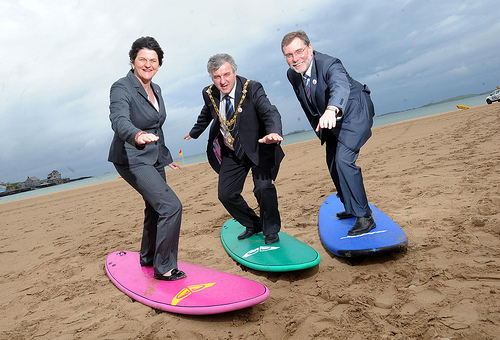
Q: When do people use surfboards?
A: When they want to surf.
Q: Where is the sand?
A: At the beach.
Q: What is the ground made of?
A: Sand.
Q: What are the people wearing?
A: Suits.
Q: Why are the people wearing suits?
A: To dress up.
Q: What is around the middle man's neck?
A: A necklace.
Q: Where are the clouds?
A: In the sky.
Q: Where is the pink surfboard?
A: On the left.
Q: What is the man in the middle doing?
A: Standing on a green board.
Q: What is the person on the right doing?
A: Standing on a blue board.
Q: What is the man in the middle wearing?
A: A business suit.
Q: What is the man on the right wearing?
A: A gray suit.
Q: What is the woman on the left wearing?
A: A business suit.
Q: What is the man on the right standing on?
A: A surfboard.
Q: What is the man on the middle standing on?
A: A surfboard.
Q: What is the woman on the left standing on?
A: Pink surfboard.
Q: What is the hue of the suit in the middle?
A: Black.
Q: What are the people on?
A: Surfboards.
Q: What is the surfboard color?
A: Pink.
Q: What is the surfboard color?
A: Green.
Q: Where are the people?
A: Beach.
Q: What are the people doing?
A: Posing.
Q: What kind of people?
A: Business.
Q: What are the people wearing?
A: Suits.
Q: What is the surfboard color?
A: Pink.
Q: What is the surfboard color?
A: Blue.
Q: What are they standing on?
A: Surf boards.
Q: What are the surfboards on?
A: They're on sand.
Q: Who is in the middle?
A: A man with grey hair.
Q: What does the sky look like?
A: Cloudy and grey.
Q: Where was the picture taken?
A: On the beach.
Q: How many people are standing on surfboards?
A: 3 people.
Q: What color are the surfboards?
A: Pink, blue, and green.